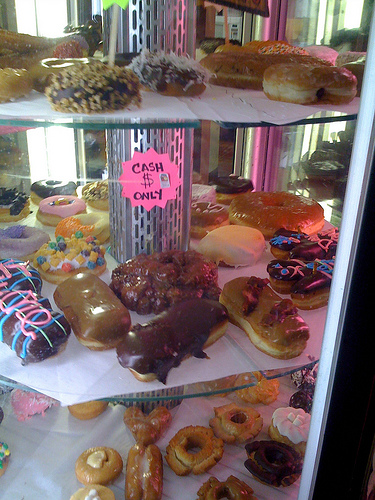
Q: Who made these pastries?
A: A baker.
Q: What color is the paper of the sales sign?
A: Pink.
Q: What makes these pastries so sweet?
A: Sugar.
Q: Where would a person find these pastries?
A: A diner.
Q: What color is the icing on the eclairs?
A: Brown.